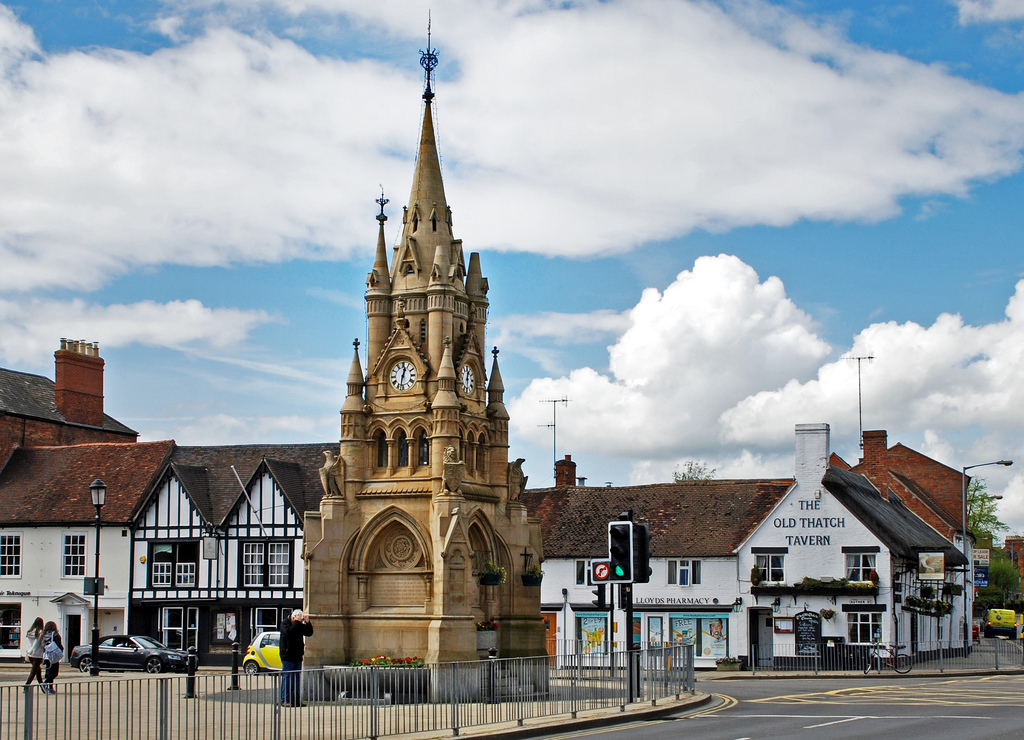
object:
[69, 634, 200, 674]
car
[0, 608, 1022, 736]
street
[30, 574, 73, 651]
people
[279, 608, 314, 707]
man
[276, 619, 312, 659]
jacket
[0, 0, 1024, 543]
clouds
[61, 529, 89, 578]
window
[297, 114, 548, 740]
clock tower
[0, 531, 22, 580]
window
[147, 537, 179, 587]
window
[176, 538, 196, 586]
window